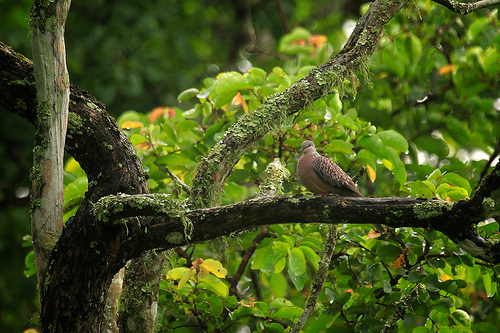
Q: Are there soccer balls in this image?
A: No, there are no soccer balls.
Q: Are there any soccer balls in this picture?
A: No, there are no soccer balls.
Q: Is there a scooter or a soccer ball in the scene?
A: No, there are no soccer balls or scooters.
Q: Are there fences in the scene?
A: No, there are no fences.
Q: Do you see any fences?
A: No, there are no fences.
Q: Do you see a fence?
A: No, there are no fences.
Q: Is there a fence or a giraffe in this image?
A: No, there are no fences or giraffes.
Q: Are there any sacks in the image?
A: No, there are no sacks.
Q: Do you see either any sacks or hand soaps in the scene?
A: No, there are no sacks or hand soaps.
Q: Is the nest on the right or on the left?
A: The nest is on the left of the image.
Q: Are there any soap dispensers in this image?
A: No, there are no soap dispensers.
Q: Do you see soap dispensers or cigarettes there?
A: No, there are no soap dispensers or cigarettes.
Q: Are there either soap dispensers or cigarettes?
A: No, there are no soap dispensers or cigarettes.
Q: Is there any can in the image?
A: No, there are no cans.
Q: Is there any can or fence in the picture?
A: No, there are no cans or fences.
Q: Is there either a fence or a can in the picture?
A: No, there are no cans or fences.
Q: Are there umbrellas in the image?
A: No, there are no umbrellas.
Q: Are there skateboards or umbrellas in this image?
A: No, there are no umbrellas or skateboards.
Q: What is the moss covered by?
A: The moss is covered by the branch.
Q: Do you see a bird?
A: Yes, there is a bird.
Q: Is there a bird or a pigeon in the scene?
A: Yes, there is a bird.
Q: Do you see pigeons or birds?
A: Yes, there is a bird.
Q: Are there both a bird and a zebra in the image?
A: No, there is a bird but no zebras.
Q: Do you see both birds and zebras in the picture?
A: No, there is a bird but no zebras.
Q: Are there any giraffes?
A: No, there are no giraffes.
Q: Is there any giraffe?
A: No, there are no giraffes.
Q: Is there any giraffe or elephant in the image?
A: No, there are no giraffes or elephants.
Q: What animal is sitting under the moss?
A: The bird is sitting under the moss.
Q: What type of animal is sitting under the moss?
A: The animal is a bird.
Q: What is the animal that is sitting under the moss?
A: The animal is a bird.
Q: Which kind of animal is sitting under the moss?
A: The animal is a bird.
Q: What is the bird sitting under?
A: The bird is sitting under the moss.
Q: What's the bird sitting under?
A: The bird is sitting under the moss.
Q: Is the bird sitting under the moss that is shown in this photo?
A: Yes, the bird is sitting under the moss.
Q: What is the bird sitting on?
A: The bird is sitting on the branch.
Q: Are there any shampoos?
A: No, there are no shampoos.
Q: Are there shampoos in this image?
A: No, there are no shampoos.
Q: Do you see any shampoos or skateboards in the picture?
A: No, there are no shampoos or skateboards.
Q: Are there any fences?
A: No, there are no fences.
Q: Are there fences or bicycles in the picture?
A: No, there are no fences or bicycles.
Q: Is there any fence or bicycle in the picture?
A: No, there are no fences or bicycles.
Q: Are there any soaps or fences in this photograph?
A: No, there are no fences or soaps.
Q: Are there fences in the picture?
A: No, there are no fences.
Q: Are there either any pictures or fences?
A: No, there are no fences or pictures.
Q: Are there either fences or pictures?
A: No, there are no fences or pictures.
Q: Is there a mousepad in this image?
A: No, there are no mouse pads.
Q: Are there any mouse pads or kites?
A: No, there are no mouse pads or kites.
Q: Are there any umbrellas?
A: No, there are no umbrellas.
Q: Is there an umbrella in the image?
A: No, there are no umbrellas.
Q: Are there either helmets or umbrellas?
A: No, there are no umbrellas or helmets.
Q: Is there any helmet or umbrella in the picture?
A: No, there are no umbrellas or helmets.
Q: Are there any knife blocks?
A: No, there are no knife blocks.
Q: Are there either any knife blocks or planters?
A: No, there are no knife blocks or planters.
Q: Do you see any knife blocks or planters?
A: No, there are no knife blocks or planters.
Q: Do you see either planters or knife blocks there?
A: No, there are no knife blocks or planters.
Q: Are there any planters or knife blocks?
A: No, there are no knife blocks or planters.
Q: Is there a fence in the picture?
A: No, there are no fences.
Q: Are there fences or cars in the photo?
A: No, there are no fences or cars.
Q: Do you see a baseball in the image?
A: No, there are no baseballs.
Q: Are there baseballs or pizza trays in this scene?
A: No, there are no baseballs or pizza trays.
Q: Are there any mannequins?
A: No, there are no mannequins.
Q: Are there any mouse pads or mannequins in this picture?
A: No, there are no mannequins or mouse pads.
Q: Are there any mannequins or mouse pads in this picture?
A: No, there are no mannequins or mouse pads.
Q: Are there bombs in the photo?
A: No, there are no bombs.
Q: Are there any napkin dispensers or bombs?
A: No, there are no bombs or napkin dispensers.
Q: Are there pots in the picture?
A: No, there are no pots.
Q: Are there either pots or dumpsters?
A: No, there are no pots or dumpsters.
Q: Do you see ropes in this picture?
A: No, there are no ropes.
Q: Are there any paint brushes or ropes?
A: No, there are no ropes or paint brushes.